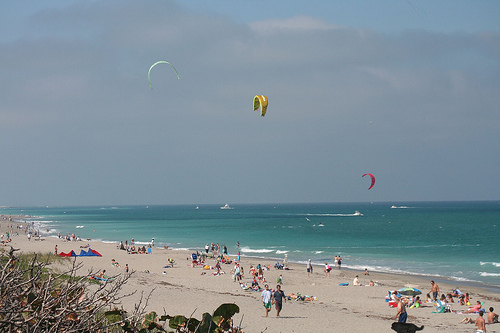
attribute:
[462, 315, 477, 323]
person — laying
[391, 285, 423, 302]
umbrella — multicolored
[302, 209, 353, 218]
wave — small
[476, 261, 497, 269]
wave — small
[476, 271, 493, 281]
wave — small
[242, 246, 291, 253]
wave — small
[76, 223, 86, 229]
wave — small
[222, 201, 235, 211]
boat — out to sea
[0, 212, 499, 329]
sand — brown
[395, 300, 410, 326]
person — shirtless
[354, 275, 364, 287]
person — sitting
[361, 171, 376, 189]
kite — red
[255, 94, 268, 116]
kite — yellow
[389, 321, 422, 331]
dog — large, black, walking